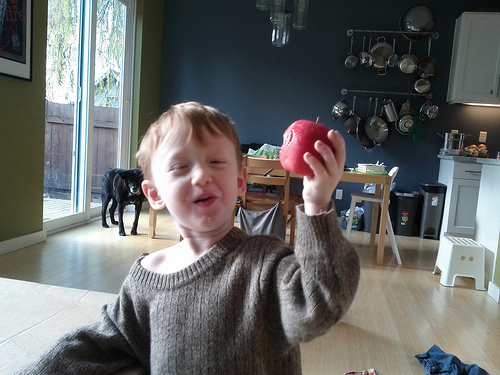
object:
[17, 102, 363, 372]
boy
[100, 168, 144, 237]
dog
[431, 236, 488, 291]
stool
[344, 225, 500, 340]
floor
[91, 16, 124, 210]
window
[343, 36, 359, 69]
pans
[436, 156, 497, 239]
cabinet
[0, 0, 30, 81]
picture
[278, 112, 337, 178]
apple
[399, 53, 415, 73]
pots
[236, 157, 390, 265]
table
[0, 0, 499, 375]
ktichen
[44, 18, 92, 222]
doors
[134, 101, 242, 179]
hair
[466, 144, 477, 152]
oranges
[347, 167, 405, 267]
chair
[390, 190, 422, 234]
box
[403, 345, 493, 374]
jeans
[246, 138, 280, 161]
fruits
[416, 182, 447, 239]
boxes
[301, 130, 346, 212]
hand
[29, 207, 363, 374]
sweater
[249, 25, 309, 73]
lamp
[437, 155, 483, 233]
counter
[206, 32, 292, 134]
blue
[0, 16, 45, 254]
wall